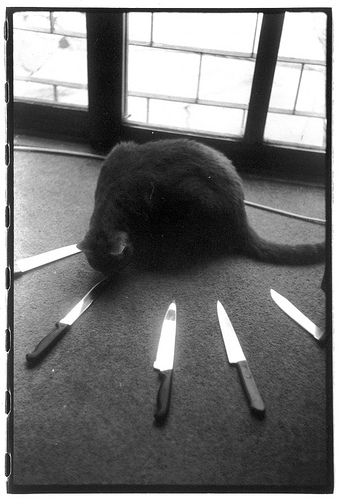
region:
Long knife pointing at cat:
[14, 231, 79, 283]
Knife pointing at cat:
[22, 267, 114, 361]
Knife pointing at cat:
[145, 293, 174, 424]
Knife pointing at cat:
[213, 297, 267, 416]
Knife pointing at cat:
[267, 284, 320, 353]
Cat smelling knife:
[75, 135, 320, 282]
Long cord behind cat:
[14, 110, 322, 224]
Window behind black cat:
[13, 11, 322, 142]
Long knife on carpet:
[211, 294, 262, 411]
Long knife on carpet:
[144, 291, 178, 425]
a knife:
[122, 266, 212, 485]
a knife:
[138, 226, 194, 454]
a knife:
[171, 306, 226, 480]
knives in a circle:
[15, 211, 313, 333]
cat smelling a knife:
[73, 217, 137, 300]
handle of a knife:
[208, 349, 260, 439]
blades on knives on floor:
[144, 294, 248, 367]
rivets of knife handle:
[239, 357, 249, 390]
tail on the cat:
[244, 233, 321, 271]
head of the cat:
[64, 222, 132, 288]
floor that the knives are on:
[28, 385, 142, 477]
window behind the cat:
[81, 41, 263, 136]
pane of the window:
[177, 52, 260, 130]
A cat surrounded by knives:
[21, 127, 328, 460]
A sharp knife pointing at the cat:
[143, 290, 183, 413]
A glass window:
[118, 11, 262, 148]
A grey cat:
[66, 144, 309, 278]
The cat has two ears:
[77, 231, 123, 256]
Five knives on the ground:
[20, 249, 320, 420]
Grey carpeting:
[27, 368, 131, 468]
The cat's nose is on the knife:
[95, 263, 120, 289]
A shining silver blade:
[150, 298, 180, 373]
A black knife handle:
[233, 350, 269, 419]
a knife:
[146, 306, 209, 433]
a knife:
[209, 305, 268, 443]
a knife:
[194, 247, 275, 496]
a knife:
[225, 247, 283, 442]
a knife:
[215, 293, 310, 494]